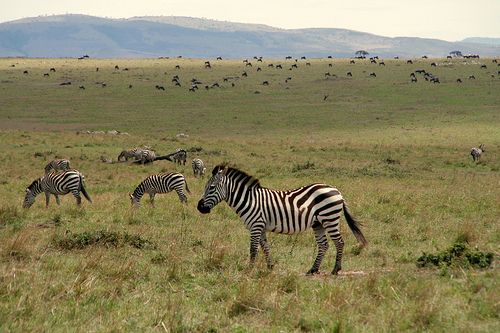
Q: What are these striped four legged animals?
A: Zebras.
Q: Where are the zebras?
A: In the wild.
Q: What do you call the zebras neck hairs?
A: Mane.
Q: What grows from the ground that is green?
A: Grass.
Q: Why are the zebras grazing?
A: For food.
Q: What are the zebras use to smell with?
A: Noses.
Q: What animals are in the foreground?
A: Those are zebra's.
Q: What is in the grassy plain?
A: Several animals.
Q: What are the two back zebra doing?
A: They are eating grass.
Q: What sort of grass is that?
A: It is thick green and brown grass.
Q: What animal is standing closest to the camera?
A: A zebra.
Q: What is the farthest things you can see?
A: Its a distant mountain range.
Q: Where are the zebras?
A: They are in a field.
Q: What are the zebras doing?
A: They are walking in the field.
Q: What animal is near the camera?
A: Zebra.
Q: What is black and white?
A: Zebras.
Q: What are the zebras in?
A: A field.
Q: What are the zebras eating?
A: Grass.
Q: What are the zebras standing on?
A: Grass.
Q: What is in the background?
A: Mountains.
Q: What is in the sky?
A: Clouds.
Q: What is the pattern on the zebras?
A: Stripes.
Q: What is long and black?
A: Zebras tail.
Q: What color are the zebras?
A: Black and white.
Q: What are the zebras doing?
A: Grazing.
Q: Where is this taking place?
A: In a grassland.